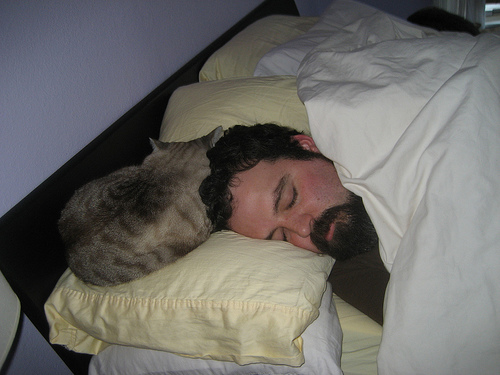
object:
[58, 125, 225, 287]
cat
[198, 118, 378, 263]
head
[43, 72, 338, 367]
pillow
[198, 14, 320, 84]
pillow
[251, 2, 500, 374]
sheet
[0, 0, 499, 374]
bed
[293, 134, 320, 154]
ear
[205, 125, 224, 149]
ear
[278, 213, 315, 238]
nose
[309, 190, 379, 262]
beard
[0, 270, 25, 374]
lampshade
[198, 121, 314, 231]
hair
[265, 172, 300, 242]
eyes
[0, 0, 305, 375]
wall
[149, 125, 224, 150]
ears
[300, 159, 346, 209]
cheek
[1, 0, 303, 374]
headboard